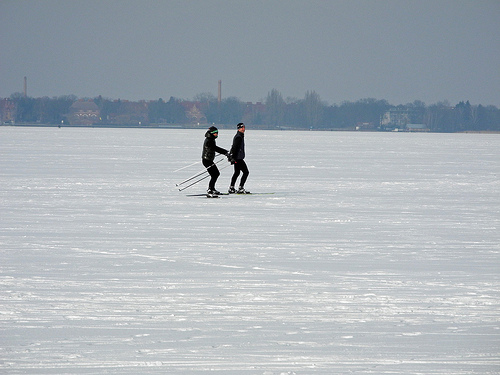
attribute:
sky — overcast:
[1, 3, 497, 108]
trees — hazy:
[1, 89, 497, 131]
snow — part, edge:
[1, 128, 498, 374]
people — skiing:
[203, 122, 249, 198]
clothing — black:
[202, 135, 249, 186]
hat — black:
[236, 122, 244, 128]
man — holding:
[230, 122, 250, 193]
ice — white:
[3, 128, 499, 374]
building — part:
[64, 94, 108, 127]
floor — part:
[3, 125, 499, 374]